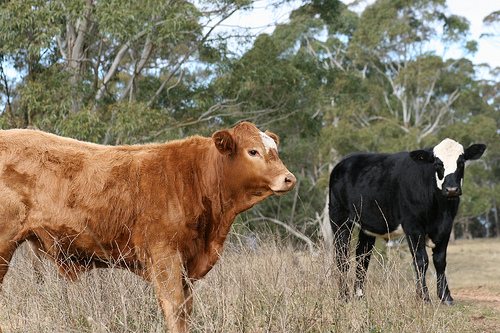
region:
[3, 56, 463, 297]
a brown and a black cow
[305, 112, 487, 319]
this cow has a white head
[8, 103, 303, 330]
a brown cow in the grass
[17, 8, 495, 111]
trees above the cows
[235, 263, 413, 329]
tall cows are in tall grass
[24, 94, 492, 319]
two cows in a picture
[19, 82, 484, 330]
this might be an altered picture with two cows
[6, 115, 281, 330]
the cow is posing in the picture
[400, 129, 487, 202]
this cow has black ears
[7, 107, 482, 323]
these two cows know they are being photographed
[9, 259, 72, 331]
patch of tall brown brush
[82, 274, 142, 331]
patch of tall brown brush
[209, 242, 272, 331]
patch of tall brown brush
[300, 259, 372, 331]
patch of tall brown brush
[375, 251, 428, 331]
patch of tall brown brush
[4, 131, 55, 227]
ruffled coat on red cow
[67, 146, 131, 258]
ruffled coat on red cow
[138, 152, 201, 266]
ruffled coat on red cow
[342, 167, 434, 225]
silky black coat on cow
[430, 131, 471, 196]
white face patch on black cow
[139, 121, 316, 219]
large red colored cow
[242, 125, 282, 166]
white spot on cows head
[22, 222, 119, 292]
fleshy bit hanging from cow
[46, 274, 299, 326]
tall brown colored grass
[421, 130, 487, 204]
cow has mostly white head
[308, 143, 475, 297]
large black colored cow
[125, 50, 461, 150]
tall green trees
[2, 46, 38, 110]
clear blue sunny day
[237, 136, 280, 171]
cow is looking at photographer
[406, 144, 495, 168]
cows ears pointed outward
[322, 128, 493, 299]
cow standing in grass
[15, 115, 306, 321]
cow standing in grass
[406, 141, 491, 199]
face of a cow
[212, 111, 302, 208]
face of a cow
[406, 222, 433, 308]
leg of a cow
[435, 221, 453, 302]
leg of a cow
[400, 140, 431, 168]
ear of a cow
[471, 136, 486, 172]
ear of a cow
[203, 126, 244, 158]
ear of a cow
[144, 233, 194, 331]
leg of a cow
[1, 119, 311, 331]
a brown cow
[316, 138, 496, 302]
a black and white cow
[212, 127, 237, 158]
the cows ear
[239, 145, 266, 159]
the cows eye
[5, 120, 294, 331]
the cow is standing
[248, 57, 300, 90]
the leaves are green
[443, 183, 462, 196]
the cows nose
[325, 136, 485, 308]
the cow is standing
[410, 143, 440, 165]
the cows ear is black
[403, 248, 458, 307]
front legs of the cow